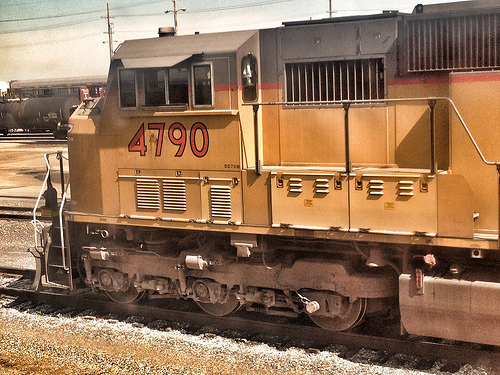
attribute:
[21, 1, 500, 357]
train — old, black, yellow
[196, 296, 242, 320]
wheel — brown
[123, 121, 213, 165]
number — red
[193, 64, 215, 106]
window — closed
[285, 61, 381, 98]
railing — metal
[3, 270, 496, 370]
tracks — set, train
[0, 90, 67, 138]
coal car — train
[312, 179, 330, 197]
ventilation slot — three, set